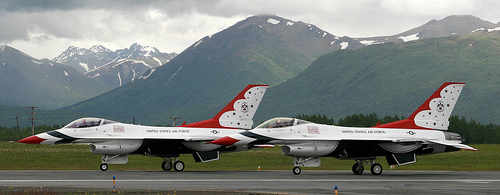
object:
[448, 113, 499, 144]
trees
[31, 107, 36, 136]
poles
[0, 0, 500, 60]
clouds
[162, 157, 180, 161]
landing gear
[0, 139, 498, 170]
grass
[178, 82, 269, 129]
tail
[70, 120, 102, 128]
men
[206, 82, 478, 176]
jet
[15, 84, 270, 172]
jet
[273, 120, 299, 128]
pilot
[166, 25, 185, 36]
white clouds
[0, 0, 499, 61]
sky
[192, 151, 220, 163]
wing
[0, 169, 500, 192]
ground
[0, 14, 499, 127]
mountains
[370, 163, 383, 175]
gear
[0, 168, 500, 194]
runway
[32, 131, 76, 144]
stripes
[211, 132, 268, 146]
stripes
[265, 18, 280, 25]
snow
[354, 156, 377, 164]
landing gear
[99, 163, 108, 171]
gear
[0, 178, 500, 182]
line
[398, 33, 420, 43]
snow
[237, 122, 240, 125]
dots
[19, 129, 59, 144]
nose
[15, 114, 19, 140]
poles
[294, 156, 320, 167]
landing gear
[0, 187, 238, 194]
concrete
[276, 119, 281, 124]
helmet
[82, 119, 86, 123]
helmet